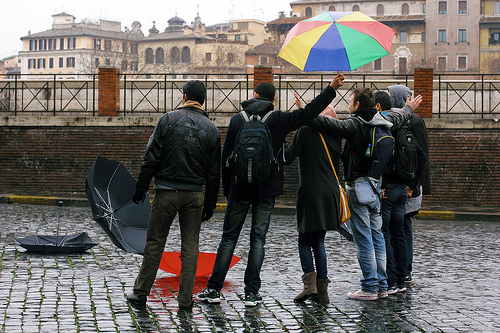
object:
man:
[122, 80, 224, 310]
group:
[122, 75, 434, 314]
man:
[197, 73, 348, 312]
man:
[293, 88, 392, 304]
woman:
[284, 100, 346, 305]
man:
[387, 82, 431, 284]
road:
[0, 203, 500, 333]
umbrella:
[274, 7, 399, 74]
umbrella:
[13, 230, 100, 257]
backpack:
[226, 110, 278, 189]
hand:
[332, 73, 346, 91]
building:
[19, 11, 146, 82]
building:
[136, 0, 216, 79]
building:
[288, 0, 499, 79]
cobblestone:
[60, 293, 76, 295]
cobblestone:
[326, 311, 344, 316]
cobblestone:
[8, 301, 24, 308]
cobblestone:
[230, 319, 245, 323]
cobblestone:
[57, 310, 78, 314]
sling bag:
[317, 129, 352, 222]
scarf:
[176, 99, 204, 112]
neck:
[181, 100, 203, 110]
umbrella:
[152, 251, 242, 278]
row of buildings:
[19, 0, 499, 80]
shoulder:
[298, 119, 322, 139]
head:
[319, 104, 339, 124]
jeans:
[205, 180, 279, 297]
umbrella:
[84, 152, 156, 258]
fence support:
[97, 66, 122, 119]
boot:
[291, 271, 319, 305]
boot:
[309, 276, 333, 305]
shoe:
[242, 290, 266, 308]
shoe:
[195, 288, 223, 306]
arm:
[379, 107, 417, 132]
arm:
[283, 85, 338, 135]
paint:
[416, 209, 456, 221]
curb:
[2, 193, 499, 222]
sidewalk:
[0, 190, 500, 224]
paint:
[214, 203, 229, 212]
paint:
[9, 194, 60, 206]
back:
[229, 108, 285, 201]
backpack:
[363, 122, 399, 180]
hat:
[321, 104, 337, 122]